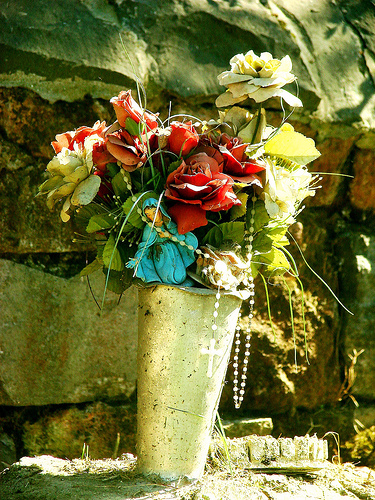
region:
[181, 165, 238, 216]
flower in the vase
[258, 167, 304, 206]
flower in the vase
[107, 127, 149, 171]
flower in the vase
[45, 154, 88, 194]
flower in the vase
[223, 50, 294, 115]
flower in the vase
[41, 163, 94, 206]
flower in the vase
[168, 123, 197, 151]
flower in the vase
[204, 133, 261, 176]
flower in the vase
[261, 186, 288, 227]
flower in the vase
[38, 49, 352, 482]
a vase of colorful flowers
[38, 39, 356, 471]
flowers displayed in a vase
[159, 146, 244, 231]
a red rose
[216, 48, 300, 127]
a white rose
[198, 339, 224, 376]
a silver cross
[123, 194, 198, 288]
the Virgin Mary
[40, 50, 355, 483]
flowers sitting on the ground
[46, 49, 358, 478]
multi-colored flowers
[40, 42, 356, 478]
flowers in a metal vase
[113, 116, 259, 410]
a metal rosary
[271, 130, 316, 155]
Light yellow petals on flower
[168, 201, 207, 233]
Red petals on flower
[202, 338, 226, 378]
Silver cross hanging from vase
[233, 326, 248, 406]
Silver beads hanging from vase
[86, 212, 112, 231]
Light green leaf in vase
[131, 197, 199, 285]
Statue of woman in blue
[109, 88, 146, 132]
Closed up red rose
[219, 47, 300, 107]
opened yellow rose in vase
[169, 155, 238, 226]
opened red rose in vase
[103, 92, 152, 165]
Group of red roses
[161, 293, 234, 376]
this is a cross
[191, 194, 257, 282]
this is a rose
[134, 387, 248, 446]
this is a stone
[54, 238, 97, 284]
this is a crack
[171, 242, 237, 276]
this is a bouquet of flowers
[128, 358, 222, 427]
this is a stone vase that is light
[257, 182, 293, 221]
this is a yellow flower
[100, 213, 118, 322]
this is a green leaf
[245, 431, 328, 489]
this is a bunch of dirt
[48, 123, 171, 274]
this is a figurine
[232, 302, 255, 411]
White beads hanging from object.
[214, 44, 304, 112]
The rose is yellow.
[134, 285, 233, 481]
A vase is setting on the ground.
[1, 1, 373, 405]
A stone wall has some sunlight on it.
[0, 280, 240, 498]
A vase is casting a shadow.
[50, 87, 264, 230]
A few red roses in a group.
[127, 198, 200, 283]
A statue of Mary with beads.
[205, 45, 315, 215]
Two yellow roses one above the other.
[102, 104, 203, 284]
Gray metal hoops in flowers to hold them together.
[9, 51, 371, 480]
A bunch of flowers in a vase with a rosary and a Madonna.